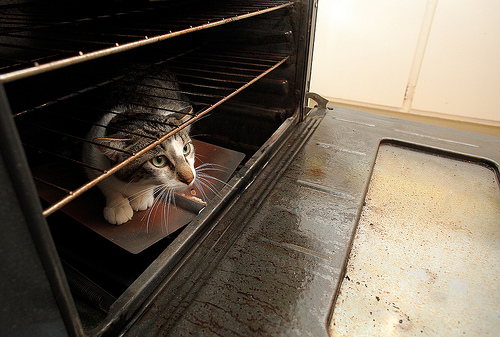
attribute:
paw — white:
[105, 195, 134, 226]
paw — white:
[125, 193, 155, 212]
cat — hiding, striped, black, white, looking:
[84, 68, 207, 230]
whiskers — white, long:
[136, 162, 240, 242]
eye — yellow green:
[149, 149, 170, 171]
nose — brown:
[177, 164, 194, 190]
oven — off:
[4, 2, 326, 331]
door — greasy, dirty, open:
[128, 76, 498, 335]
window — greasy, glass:
[334, 132, 499, 336]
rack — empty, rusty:
[0, 4, 296, 218]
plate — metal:
[33, 105, 245, 259]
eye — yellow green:
[183, 138, 194, 160]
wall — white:
[298, 0, 496, 128]